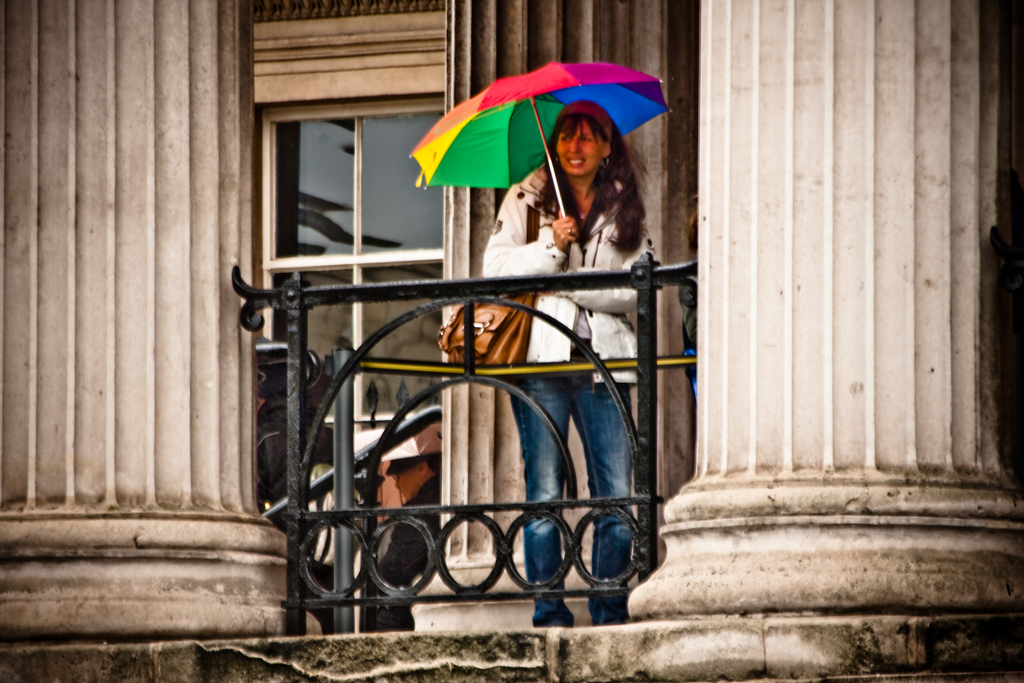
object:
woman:
[476, 94, 650, 633]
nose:
[567, 128, 584, 155]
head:
[554, 99, 617, 177]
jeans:
[511, 354, 653, 628]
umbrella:
[402, 63, 677, 235]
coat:
[473, 171, 668, 377]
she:
[476, 100, 663, 626]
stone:
[904, 612, 987, 658]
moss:
[915, 612, 991, 662]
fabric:
[405, 55, 674, 198]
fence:
[228, 243, 702, 630]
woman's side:
[462, 175, 561, 619]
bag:
[436, 280, 539, 370]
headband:
[556, 101, 614, 143]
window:
[260, 85, 440, 427]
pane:
[268, 100, 351, 261]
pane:
[358, 107, 441, 255]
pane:
[362, 262, 436, 433]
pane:
[276, 266, 356, 414]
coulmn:
[632, 0, 1023, 613]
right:
[435, 14, 993, 652]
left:
[11, 16, 413, 675]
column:
[0, 0, 274, 629]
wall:
[5, 4, 256, 494]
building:
[6, 4, 1022, 676]